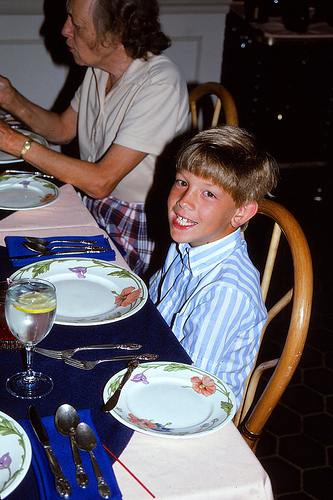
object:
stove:
[235, 16, 332, 174]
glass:
[4, 277, 57, 399]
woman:
[0, 0, 193, 279]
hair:
[91, 0, 173, 61]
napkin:
[17, 407, 122, 497]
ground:
[140, 235, 333, 497]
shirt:
[148, 227, 269, 421]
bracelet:
[18, 138, 33, 157]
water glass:
[3, 275, 58, 402]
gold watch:
[20, 134, 33, 159]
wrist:
[9, 85, 22, 117]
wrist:
[9, 128, 28, 161]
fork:
[34, 341, 159, 372]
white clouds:
[2, 225, 119, 273]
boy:
[147, 123, 280, 411]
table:
[0, 107, 273, 500]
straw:
[100, 441, 155, 498]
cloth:
[146, 229, 267, 413]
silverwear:
[15, 249, 107, 260]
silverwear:
[24, 241, 105, 250]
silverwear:
[24, 235, 98, 246]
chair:
[239, 196, 314, 453]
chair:
[182, 78, 243, 134]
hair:
[174, 123, 281, 208]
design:
[109, 358, 235, 441]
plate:
[5, 255, 149, 326]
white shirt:
[68, 46, 193, 210]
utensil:
[8, 234, 108, 261]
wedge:
[14, 292, 56, 314]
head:
[164, 125, 281, 242]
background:
[0, 0, 332, 195]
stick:
[98, 439, 164, 497]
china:
[101, 361, 237, 438]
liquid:
[3, 281, 55, 349]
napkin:
[3, 234, 116, 269]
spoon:
[22, 237, 97, 248]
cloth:
[0, 108, 275, 500]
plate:
[0, 173, 59, 209]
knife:
[28, 400, 72, 499]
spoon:
[53, 402, 87, 488]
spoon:
[72, 420, 111, 498]